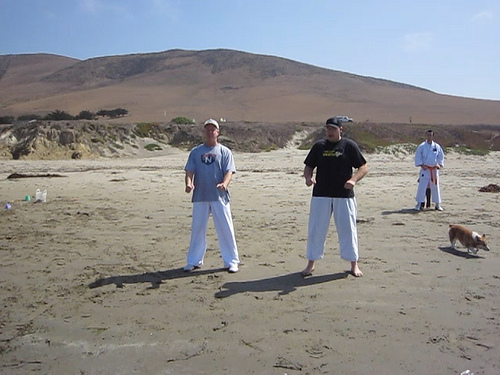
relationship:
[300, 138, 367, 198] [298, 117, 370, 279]
black shirt on man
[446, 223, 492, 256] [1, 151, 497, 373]
dog on beach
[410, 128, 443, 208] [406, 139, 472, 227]
man in karate outfit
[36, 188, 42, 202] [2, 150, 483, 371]
bottle in sand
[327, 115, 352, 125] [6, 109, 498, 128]
truck parked on road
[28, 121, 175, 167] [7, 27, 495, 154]
dunes of sand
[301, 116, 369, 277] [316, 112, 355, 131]
man wearing cap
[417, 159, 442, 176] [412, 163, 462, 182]
belt around mans waist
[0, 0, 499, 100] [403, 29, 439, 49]
sky with cloud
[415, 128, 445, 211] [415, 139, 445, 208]
man wearing clothing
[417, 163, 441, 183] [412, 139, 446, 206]
belt on clothing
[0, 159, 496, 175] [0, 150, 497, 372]
road on ground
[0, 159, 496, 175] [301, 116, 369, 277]
road of man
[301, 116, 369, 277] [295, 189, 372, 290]
man wears pants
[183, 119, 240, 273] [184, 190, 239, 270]
man wears pants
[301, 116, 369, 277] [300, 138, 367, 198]
man wears black shirt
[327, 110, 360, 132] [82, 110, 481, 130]
truck on road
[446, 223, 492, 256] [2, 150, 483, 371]
dog walking on sand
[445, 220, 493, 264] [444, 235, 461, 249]
dog has short leg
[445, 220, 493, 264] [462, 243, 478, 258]
dog has short leg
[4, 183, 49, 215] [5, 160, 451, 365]
trash on shore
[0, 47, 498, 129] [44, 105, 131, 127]
hill with trees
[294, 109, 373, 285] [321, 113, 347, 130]
man wearing cap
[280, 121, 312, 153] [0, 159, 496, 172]
path leading to road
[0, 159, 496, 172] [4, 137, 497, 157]
road leading to shore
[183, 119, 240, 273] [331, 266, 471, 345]
man on sand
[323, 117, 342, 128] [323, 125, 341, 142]
cap on head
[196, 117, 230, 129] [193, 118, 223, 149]
hat on head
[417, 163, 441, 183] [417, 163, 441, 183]
belt on belt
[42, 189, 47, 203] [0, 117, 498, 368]
bottle on beach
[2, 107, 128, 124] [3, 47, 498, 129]
trees on side of hill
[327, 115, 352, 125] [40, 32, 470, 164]
truck on hilltop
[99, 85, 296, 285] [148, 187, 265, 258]
man wearing pants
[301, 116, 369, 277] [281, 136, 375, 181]
man wearing black shirt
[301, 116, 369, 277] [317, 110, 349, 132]
man wearing hat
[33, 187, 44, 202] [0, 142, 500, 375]
bottle on beach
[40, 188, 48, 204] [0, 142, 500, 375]
bottle on beach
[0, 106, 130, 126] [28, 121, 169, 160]
trees on dunes